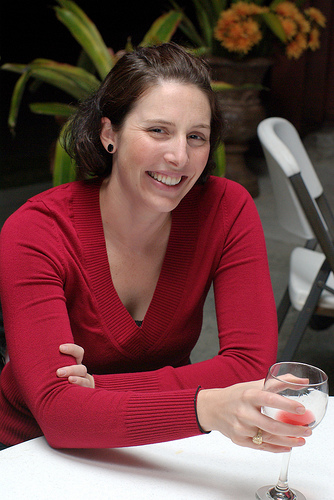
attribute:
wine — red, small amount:
[271, 406, 318, 441]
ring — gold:
[248, 425, 266, 448]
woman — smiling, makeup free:
[1, 39, 315, 456]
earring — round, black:
[105, 143, 115, 154]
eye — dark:
[146, 124, 170, 138]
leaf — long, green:
[47, 5, 112, 82]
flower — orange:
[303, 6, 332, 29]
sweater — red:
[0, 172, 281, 456]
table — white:
[0, 372, 333, 499]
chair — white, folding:
[254, 115, 333, 375]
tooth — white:
[160, 173, 169, 185]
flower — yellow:
[285, 32, 308, 61]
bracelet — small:
[192, 384, 211, 435]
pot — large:
[196, 52, 266, 201]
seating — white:
[288, 243, 333, 318]